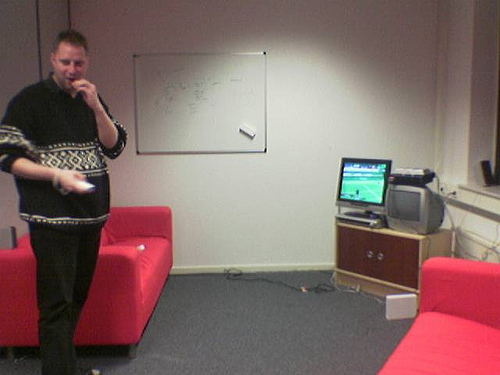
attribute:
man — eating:
[1, 29, 129, 372]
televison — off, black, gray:
[385, 185, 448, 232]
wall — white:
[1, 0, 439, 272]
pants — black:
[27, 223, 104, 375]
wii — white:
[383, 293, 418, 322]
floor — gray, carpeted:
[1, 273, 419, 372]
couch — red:
[375, 256, 499, 373]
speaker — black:
[482, 159, 493, 187]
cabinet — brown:
[334, 218, 452, 304]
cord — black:
[226, 266, 334, 291]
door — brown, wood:
[338, 226, 420, 289]